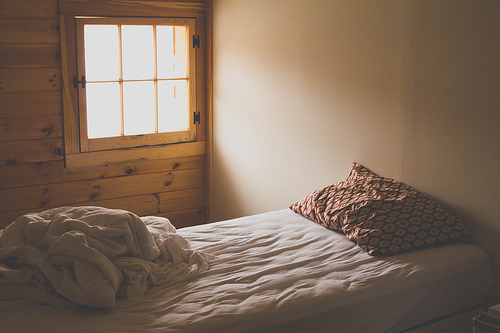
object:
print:
[378, 200, 432, 240]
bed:
[0, 189, 498, 332]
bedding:
[0, 204, 211, 313]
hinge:
[71, 73, 88, 92]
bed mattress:
[58, 203, 491, 330]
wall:
[210, 5, 293, 216]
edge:
[471, 303, 499, 333]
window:
[77, 17, 198, 152]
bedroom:
[1, 0, 498, 331]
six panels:
[83, 25, 190, 138]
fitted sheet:
[157, 208, 489, 331]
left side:
[64, 15, 86, 169]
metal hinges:
[187, 33, 207, 52]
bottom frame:
[188, 110, 206, 130]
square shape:
[62, 3, 204, 162]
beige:
[210, 4, 500, 160]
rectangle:
[0, 189, 494, 332]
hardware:
[189, 33, 207, 126]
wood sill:
[63, 135, 210, 170]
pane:
[124, 82, 158, 132]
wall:
[13, 3, 85, 227]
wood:
[17, 168, 96, 192]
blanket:
[0, 202, 161, 311]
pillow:
[285, 157, 473, 255]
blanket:
[138, 197, 220, 302]